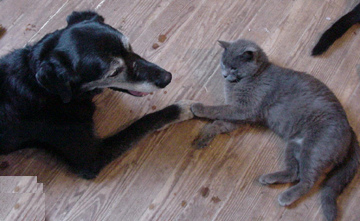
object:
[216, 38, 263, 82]
head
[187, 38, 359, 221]
cat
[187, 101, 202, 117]
paw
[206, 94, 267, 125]
legs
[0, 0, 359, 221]
floor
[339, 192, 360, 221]
flooring slats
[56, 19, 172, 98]
head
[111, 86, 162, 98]
mouth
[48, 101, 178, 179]
leg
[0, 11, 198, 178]
dog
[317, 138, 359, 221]
tail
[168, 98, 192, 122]
paw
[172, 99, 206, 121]
pair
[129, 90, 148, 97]
tongue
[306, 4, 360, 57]
tail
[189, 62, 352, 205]
body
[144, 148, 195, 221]
strips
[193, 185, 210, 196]
spots